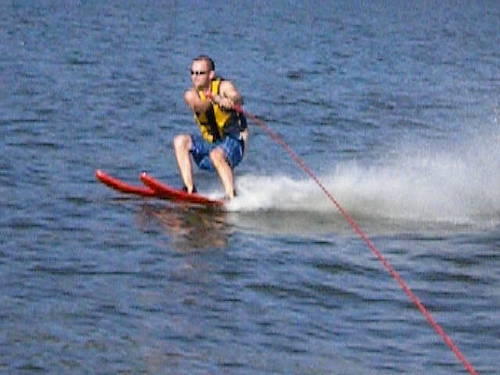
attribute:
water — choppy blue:
[157, 228, 257, 354]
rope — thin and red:
[330, 201, 378, 260]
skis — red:
[79, 160, 234, 229]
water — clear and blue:
[281, 57, 416, 141]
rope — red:
[241, 101, 472, 372]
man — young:
[171, 54, 249, 197]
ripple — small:
[28, 259, 163, 279]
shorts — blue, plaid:
[185, 130, 244, 172]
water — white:
[209, 125, 499, 239]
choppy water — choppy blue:
[91, 246, 379, 330]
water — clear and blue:
[324, 22, 381, 64]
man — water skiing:
[154, 55, 249, 196]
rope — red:
[225, 104, 492, 328]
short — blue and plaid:
[186, 135, 246, 172]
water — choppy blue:
[362, 23, 474, 100]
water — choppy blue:
[176, 264, 324, 327]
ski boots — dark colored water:
[204, 184, 224, 274]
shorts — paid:
[157, 123, 271, 175]